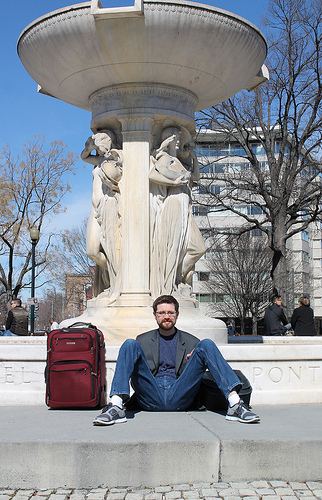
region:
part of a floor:
[221, 414, 231, 426]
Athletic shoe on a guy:
[224, 400, 259, 423]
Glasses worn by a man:
[153, 309, 176, 315]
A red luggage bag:
[45, 320, 105, 410]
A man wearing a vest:
[3, 297, 29, 335]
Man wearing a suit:
[263, 295, 288, 333]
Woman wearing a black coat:
[291, 296, 317, 334]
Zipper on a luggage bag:
[54, 335, 59, 345]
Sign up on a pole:
[27, 296, 37, 304]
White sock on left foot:
[227, 393, 240, 406]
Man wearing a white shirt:
[48, 317, 58, 329]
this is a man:
[116, 292, 285, 431]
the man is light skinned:
[158, 316, 170, 323]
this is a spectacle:
[142, 308, 173, 320]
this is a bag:
[43, 326, 94, 402]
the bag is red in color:
[58, 373, 82, 398]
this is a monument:
[71, 125, 130, 247]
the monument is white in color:
[89, 135, 105, 214]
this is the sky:
[6, 92, 45, 143]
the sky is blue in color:
[12, 93, 39, 122]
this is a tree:
[10, 143, 50, 208]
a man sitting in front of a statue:
[91, 294, 259, 426]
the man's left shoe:
[92, 401, 126, 425]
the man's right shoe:
[225, 398, 260, 422]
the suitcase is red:
[43, 320, 106, 409]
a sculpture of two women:
[80, 124, 206, 298]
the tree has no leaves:
[191, 0, 321, 334]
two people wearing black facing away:
[259, 294, 314, 336]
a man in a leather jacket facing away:
[0, 297, 28, 336]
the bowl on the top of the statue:
[16, 0, 269, 111]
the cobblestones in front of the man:
[0, 479, 321, 499]